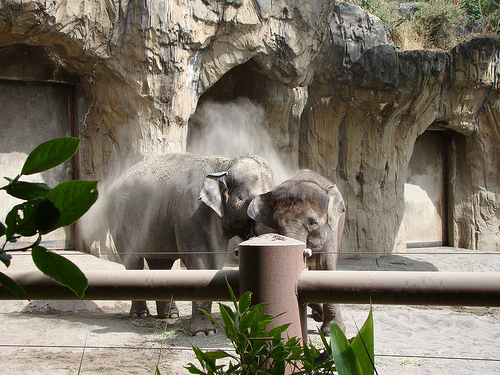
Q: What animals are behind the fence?
A: Elephants.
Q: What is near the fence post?
A: Leaves.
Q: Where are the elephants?
A: In a zoo.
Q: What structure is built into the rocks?
A: Door to the animal's night enclosures.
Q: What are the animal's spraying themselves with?
A: Dust.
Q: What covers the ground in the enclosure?
A: Dirt.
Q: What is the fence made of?
A: Poles and wire fencing.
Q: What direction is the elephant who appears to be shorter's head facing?
A: Towards me.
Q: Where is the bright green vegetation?
A: In front of the railing.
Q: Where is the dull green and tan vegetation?
A: On top of the rock.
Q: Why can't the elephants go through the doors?
A: The doors are closed.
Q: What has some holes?
A: Green leaves.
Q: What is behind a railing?
A: Elephants.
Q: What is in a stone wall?
A: A door.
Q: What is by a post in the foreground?
A: Green foliage.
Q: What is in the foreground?
A: Post and green leaves.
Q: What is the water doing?
A: Flowing from mouth in wall.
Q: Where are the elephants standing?
A: Behind a railing in a zoo.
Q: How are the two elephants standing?
A: They are standing together.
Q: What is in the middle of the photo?
A: Heads of two elephants and a post.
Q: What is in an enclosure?
A: An elephant.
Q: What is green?
A: The leaves.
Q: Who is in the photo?
A: Elephants.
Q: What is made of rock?
A: The wall.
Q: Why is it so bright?
A: Sunny.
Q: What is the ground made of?
A: Dirt.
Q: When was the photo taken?
A: Day time.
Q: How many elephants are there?
A: Two.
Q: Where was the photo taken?
A: At the zoo.